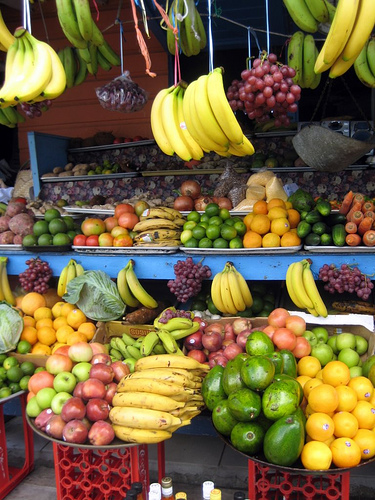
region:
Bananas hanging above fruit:
[160, 67, 231, 155]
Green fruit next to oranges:
[230, 350, 263, 460]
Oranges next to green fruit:
[302, 372, 359, 466]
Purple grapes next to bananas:
[325, 260, 363, 306]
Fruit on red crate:
[36, 425, 106, 495]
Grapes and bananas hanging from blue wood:
[12, 261, 348, 293]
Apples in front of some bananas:
[199, 316, 249, 377]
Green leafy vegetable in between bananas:
[68, 265, 126, 335]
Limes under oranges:
[9, 357, 42, 389]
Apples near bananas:
[72, 369, 117, 467]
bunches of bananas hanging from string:
[2, 0, 374, 147]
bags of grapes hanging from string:
[19, 56, 298, 121]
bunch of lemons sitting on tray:
[242, 190, 300, 248]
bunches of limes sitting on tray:
[181, 200, 242, 245]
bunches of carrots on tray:
[339, 186, 371, 244]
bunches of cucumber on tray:
[297, 184, 343, 244]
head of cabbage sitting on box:
[69, 270, 124, 326]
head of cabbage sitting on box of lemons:
[0, 297, 21, 357]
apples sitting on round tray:
[21, 343, 126, 444]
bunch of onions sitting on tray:
[176, 182, 230, 210]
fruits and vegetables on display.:
[15, 8, 354, 383]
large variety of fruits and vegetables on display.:
[15, 60, 363, 405]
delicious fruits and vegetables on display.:
[18, 32, 348, 362]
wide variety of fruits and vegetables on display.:
[25, 15, 365, 383]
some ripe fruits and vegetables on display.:
[20, 37, 358, 370]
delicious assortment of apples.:
[41, 360, 114, 448]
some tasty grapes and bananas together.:
[158, 253, 252, 311]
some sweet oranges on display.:
[243, 194, 305, 249]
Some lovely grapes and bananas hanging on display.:
[148, 31, 306, 156]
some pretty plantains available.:
[52, 1, 127, 79]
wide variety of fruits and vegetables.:
[1, 18, 361, 365]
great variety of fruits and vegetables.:
[19, 131, 352, 461]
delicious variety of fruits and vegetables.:
[25, 127, 355, 444]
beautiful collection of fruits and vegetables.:
[11, 30, 360, 450]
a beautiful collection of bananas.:
[210, 263, 252, 304]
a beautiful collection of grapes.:
[160, 255, 209, 295]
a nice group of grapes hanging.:
[228, 30, 299, 120]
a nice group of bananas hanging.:
[150, 60, 247, 153]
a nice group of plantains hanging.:
[51, 1, 114, 66]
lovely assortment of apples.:
[55, 360, 110, 442]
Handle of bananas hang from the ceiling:
[0, 0, 76, 114]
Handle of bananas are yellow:
[0, 21, 73, 112]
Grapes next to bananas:
[156, 253, 213, 307]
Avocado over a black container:
[196, 320, 314, 475]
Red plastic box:
[43, 447, 159, 498]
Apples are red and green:
[16, 331, 126, 451]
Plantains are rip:
[129, 200, 185, 260]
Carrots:
[339, 182, 373, 251]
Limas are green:
[172, 195, 248, 260]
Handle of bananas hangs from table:
[201, 250, 266, 315]